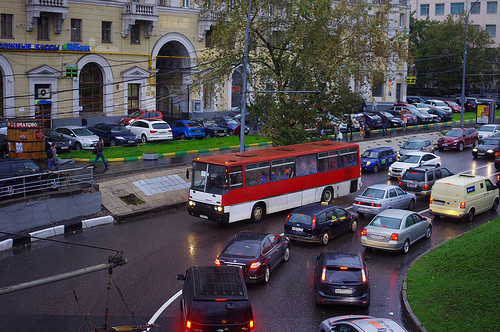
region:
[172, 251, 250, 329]
this is a car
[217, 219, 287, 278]
this is a car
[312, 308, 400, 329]
this is a car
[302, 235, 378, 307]
this is a car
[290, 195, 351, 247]
this is a car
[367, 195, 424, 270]
this is a car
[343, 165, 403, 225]
this is a car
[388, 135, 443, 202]
this is a car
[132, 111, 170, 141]
this is a car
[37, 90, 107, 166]
this is a car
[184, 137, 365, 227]
The bus is red and white.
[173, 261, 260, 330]
The car's lights are on.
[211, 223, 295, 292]
The car's lights are on.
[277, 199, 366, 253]
The car's lights are on.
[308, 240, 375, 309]
The car's lights are on.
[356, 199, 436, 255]
The car's lights are on.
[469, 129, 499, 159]
The car's lights are on.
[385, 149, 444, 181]
The car's lights are on.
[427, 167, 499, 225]
The car's lights are on.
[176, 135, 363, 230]
The bus's lights are on.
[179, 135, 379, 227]
bus is red and white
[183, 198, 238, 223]
bus's lights are on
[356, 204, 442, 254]
the car is silver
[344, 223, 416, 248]
car's tail lights are red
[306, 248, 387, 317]
the car is black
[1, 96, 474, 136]
cars parked near building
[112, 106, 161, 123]
the car is red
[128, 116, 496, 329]
bus driving in opposite direction from cars on right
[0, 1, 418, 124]
the building is yellow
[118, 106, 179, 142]
the car is white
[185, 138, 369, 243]
The bus is red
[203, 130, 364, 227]
The bus has passengers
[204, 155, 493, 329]
There is a traffic jam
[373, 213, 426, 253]
the car is silver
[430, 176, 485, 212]
the van has no back windows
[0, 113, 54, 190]
the sign is wooden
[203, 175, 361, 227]
the bottom of the bus is white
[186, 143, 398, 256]
the bus is on the street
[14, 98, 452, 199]
many cars are parked outside the building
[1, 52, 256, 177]
electrical wires hang down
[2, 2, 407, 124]
a yellow building with white accents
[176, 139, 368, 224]
a red and white bus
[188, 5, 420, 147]
a tree along the median strip of the road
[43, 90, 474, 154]
cars parked in front of the building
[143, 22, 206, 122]
large arch over the main entry way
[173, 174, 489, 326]
cars following the curved road to the right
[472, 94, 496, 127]
advertisement sign on the sidewalk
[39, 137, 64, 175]
man wearing a back pack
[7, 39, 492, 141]
street posts connecting electrical wires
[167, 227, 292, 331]
cars with their back lights on